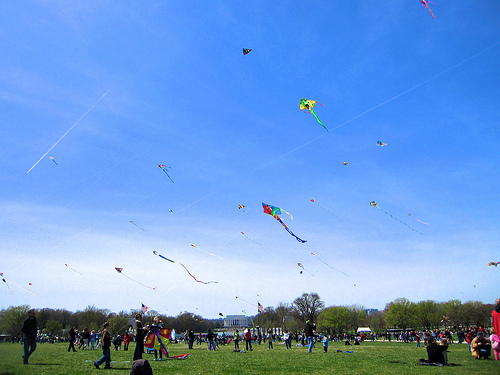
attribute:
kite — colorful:
[258, 201, 310, 251]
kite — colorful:
[111, 220, 338, 298]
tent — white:
[353, 326, 369, 332]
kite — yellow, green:
[283, 87, 359, 152]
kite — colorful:
[340, 187, 456, 249]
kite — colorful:
[258, 197, 325, 264]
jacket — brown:
[469, 336, 483, 355]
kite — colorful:
[296, 97, 329, 132]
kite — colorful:
[240, 46, 250, 57]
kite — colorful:
[375, 139, 388, 151]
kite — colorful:
[485, 261, 498, 269]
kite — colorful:
[339, 158, 353, 171]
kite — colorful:
[188, 89, 446, 266]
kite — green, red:
[215, 152, 378, 273]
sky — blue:
[419, 101, 496, 240]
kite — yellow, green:
[298, 93, 330, 133]